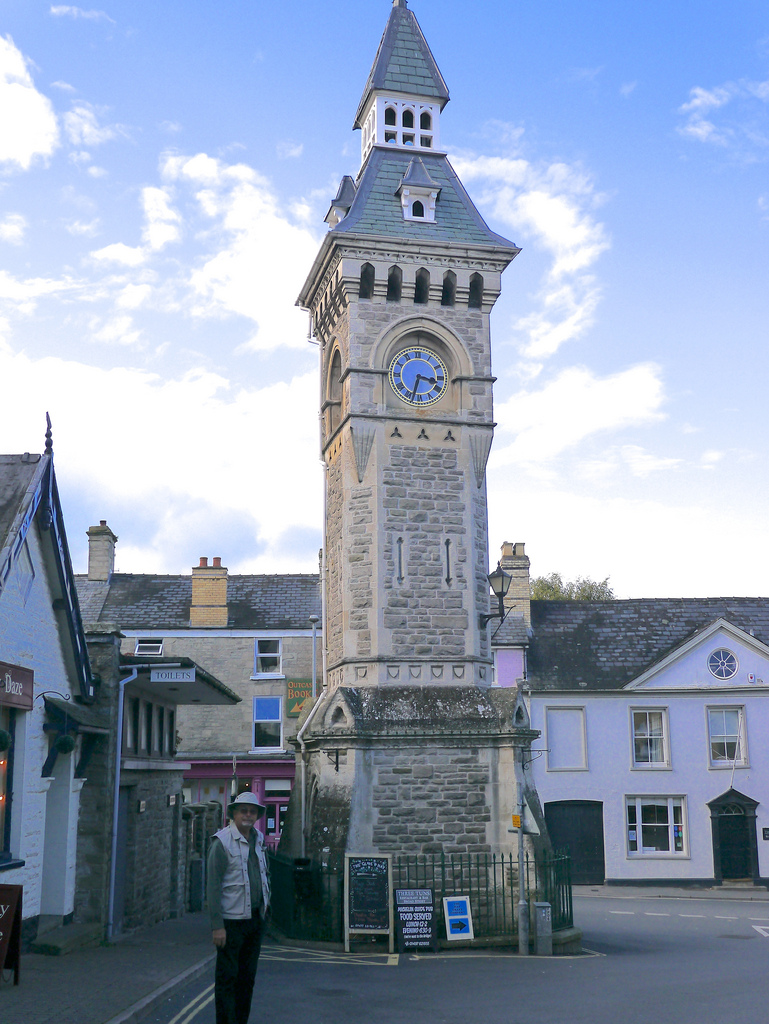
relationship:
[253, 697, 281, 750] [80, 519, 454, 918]
window on building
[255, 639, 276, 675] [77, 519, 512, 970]
window on building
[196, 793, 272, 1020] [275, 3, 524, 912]
man next to tower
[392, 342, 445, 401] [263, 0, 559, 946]
clock on tower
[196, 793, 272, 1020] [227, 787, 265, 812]
man wearing hat